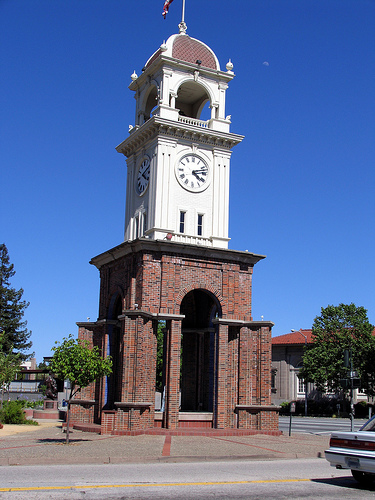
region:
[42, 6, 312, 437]
This is a clock tower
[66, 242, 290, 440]
The base of the tower is made of brick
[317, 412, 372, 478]
A white car on the road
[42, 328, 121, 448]
A small tree growing near the tower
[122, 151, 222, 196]
The numbers are roman numerals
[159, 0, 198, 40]
The flag is on top of the tower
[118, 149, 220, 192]
The clock faces are round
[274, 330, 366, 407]
A small building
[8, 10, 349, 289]
Bright blue sky behind the tower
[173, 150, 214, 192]
a clock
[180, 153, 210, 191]
a clock on the building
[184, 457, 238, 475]
the street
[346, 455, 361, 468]
a license plate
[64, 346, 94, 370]
the bush is green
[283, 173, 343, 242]
the sky is clear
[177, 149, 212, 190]
a white clock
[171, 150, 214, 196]
the clock is white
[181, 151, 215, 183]
the clock is white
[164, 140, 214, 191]
the clock is white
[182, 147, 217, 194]
the clock is white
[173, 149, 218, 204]
the clock is white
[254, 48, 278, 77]
a moon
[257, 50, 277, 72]
a moon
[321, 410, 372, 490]
Car on the road.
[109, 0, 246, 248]
Tower on the building.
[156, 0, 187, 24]
Flag on the pole.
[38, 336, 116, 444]
Tree in the forefront.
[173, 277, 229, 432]
Arched opening in the structure.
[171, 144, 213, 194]
clock on the building.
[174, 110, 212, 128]
White railing on the building.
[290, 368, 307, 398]
Window in the building.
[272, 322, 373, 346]
Red roof on the building.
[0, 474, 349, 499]
Yellow line on the road.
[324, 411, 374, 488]
rear of a white compact car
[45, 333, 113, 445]
small deciduous tree planted in the sidewalk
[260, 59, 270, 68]
moon is showing in the daytime sky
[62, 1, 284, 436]
old clock tower on a corner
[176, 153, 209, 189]
round white clock with Roman numerals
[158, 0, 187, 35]
flag on a metal pole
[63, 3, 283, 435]
base of clock tower is made of red brick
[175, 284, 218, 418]
arched doorway in the clock tower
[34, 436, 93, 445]
shadow of a tree on the ground